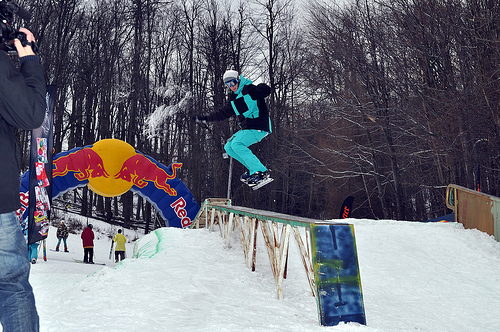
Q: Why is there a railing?
A: For snowboarders.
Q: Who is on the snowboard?
A: The snowboarder.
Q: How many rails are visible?
A: One.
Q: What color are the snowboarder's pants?
A: Blue.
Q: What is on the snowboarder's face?
A: Goggles.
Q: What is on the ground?
A: Snow.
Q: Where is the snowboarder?
A: In the air.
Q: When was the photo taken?
A: Daytime.